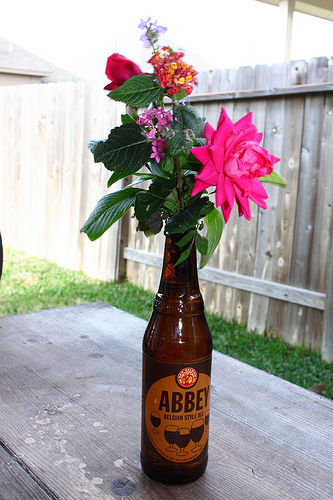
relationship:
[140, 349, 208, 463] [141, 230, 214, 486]
label on beer bottle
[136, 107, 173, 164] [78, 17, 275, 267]
flower in cluster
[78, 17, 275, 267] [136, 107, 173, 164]
cluster of flower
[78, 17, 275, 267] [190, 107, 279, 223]
cluster of flower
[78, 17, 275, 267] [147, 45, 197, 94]
cluster of flower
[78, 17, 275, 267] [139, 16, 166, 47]
cluster of flower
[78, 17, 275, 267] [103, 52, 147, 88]
cluster of flower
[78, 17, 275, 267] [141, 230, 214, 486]
cluster in beer bottle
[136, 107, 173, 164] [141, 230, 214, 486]
flower in beer bottle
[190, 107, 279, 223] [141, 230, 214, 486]
flower in beer bottle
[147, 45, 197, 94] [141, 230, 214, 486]
flower in beer bottle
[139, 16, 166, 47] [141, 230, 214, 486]
flower in beer bottle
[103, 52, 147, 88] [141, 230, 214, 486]
flower in beer bottle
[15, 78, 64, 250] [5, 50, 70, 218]
plank on wall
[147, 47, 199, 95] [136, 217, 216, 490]
flower are on bottle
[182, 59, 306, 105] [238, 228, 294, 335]
plank on wall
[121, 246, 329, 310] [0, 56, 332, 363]
plank on wall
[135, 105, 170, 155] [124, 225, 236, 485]
flower in beer bottle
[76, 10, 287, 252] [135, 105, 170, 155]
flower cluster of flower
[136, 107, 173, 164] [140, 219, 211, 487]
flower in a beer bottle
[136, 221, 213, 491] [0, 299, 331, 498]
vase sitting on wooden table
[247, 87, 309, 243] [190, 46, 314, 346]
plank on wall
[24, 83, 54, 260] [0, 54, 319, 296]
plank on wall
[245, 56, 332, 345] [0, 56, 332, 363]
plank on wall